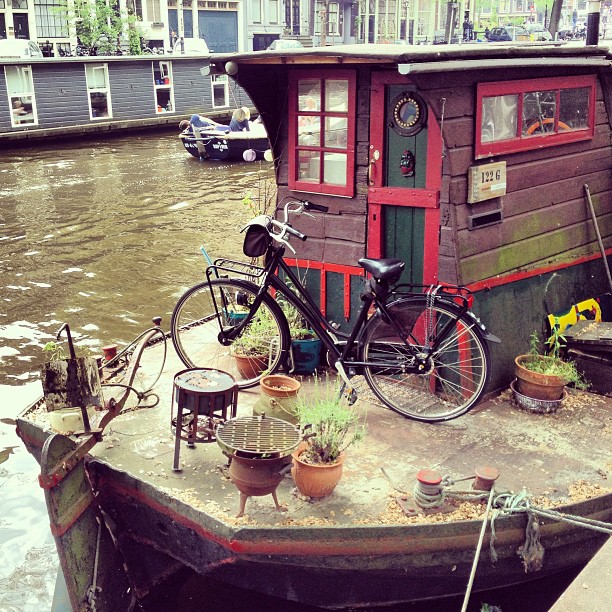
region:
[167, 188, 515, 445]
this is a bike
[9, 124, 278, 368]
a body of water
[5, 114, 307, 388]
the water is green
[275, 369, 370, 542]
a small potted plant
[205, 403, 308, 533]
a small grill set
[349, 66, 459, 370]
green door on house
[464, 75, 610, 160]
window on the house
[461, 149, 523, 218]
address on the house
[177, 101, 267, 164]
blue and white boat on the water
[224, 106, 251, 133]
woman in blue shirt inside a blue boat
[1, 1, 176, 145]
blue house beside the water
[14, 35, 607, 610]
red boat in the water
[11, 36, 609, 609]
boat tied to the deck with rope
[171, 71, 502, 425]
bicycle in front of a door of a boat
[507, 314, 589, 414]
plant inside a clay pot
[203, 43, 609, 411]
small house on top of a boat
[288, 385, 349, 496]
a plant in a pot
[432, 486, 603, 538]
ropes on the boat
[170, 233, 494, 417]
a black bicycle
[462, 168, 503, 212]
a sign on the building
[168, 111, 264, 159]
a small black boat in the water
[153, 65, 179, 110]
a window on the blue house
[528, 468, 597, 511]
leaves on the boat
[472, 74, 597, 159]
glass window with red frame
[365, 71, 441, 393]
wood door with red frame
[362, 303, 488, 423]
black rubber bike tire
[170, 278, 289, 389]
black rubber bike tire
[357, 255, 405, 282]
black leather bike seat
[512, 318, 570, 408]
brown clay planter with plant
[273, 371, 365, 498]
brown clay planter with plant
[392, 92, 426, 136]
round window in a door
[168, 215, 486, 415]
a black bicycle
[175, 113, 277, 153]
a boat in the water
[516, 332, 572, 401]
a small potted plant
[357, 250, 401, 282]
the seat on the bike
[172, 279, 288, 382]
the tire on the bike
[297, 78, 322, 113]
glass is clean and clear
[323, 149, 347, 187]
glass is clean and clear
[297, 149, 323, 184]
glass is clean and clear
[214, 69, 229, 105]
glass is clean and clear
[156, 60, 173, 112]
glass is clean and clear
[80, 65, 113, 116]
glass is clean and clear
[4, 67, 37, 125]
glass is clean and clear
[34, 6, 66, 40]
glass is clean and clear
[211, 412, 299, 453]
The metal dish on the vase.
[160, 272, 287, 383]
The front wheel of the bike.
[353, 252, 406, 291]
The black seat on the bike.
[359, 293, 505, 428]
The black wheel on the bike.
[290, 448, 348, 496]
The vase made of clay.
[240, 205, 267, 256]
The bag on the front of the bike.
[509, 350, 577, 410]
The vase on the right.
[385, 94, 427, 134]
The mirror on the building.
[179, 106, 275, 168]
The small boat in the water.